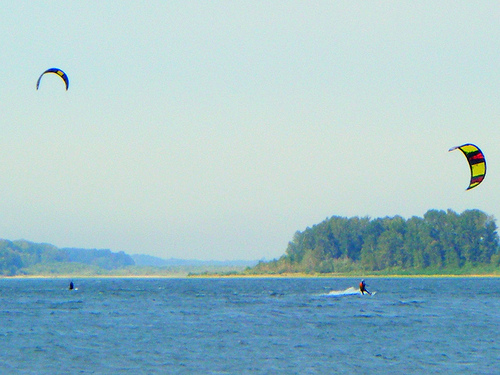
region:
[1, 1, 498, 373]
a daytime scene of kite boarders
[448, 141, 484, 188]
a yellow, red and black kite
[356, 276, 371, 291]
a kite boarder wearing an orange vest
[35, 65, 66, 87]
a blue and yellow kite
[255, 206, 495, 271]
tall trees at the shoreline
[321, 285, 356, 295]
a small wake from the kite boarder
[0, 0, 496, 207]
the sky is hazy but free of clouds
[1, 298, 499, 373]
choppy water on the lake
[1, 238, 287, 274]
tall trees in the distance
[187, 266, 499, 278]
green vegetation on the shore line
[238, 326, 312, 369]
The water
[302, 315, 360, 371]
The water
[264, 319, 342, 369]
The water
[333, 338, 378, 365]
The water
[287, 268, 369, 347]
The water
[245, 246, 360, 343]
The water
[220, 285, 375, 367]
The water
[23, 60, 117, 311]
windsurfer in the water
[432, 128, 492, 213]
red and black kite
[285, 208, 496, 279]
tall green trees on the shore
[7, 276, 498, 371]
large blue body of water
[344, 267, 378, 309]
windsurfer standing in the water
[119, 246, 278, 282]
mountain behind the trees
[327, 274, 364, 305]
white wake behind the surfer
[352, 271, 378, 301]
windsurfer wearing red vest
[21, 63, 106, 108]
blue and yellow kite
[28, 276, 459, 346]
water is calm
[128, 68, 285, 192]
The sky is cloudy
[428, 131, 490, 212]
The kite is yellow, red and blue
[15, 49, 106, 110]
The kite is blue.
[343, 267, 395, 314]
He is kite surfing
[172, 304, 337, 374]
The water is calm.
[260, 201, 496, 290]
The island has trees.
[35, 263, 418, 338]
They are on the water.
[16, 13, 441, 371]
It is summer and hot outside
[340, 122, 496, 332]
He is hanging on to the string.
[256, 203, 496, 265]
The trees are green and leafy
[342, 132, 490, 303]
a man parasailing in the water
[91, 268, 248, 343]
dark blue water with no waves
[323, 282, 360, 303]
white cast off the waves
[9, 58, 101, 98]
parasail shoot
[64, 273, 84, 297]
a person in the water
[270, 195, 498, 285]
a patch of green trees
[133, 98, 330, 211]
a gray sky with no sun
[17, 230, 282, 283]
mountains off in the distance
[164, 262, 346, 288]
beach on the shore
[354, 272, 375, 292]
man wearing a red shirt